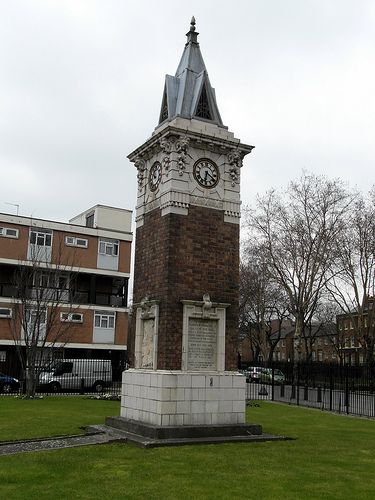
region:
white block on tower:
[157, 415, 167, 428]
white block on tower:
[173, 415, 182, 425]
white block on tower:
[163, 373, 176, 386]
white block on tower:
[178, 374, 193, 387]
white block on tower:
[191, 375, 207, 387]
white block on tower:
[207, 376, 223, 387]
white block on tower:
[220, 371, 235, 386]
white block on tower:
[234, 376, 247, 387]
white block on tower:
[166, 388, 183, 400]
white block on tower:
[193, 390, 204, 397]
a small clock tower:
[85, 13, 292, 449]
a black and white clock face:
[193, 158, 219, 189]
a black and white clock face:
[148, 159, 161, 190]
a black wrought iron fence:
[0, 358, 129, 394]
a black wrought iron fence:
[232, 365, 272, 400]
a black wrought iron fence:
[270, 365, 373, 421]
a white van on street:
[36, 358, 111, 392]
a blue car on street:
[0, 370, 19, 390]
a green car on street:
[259, 364, 284, 384]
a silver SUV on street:
[243, 366, 261, 382]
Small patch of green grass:
[284, 455, 314, 480]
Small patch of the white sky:
[84, 99, 105, 116]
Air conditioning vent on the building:
[65, 233, 89, 249]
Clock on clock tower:
[195, 159, 220, 195]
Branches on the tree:
[23, 270, 55, 302]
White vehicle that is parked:
[41, 356, 116, 393]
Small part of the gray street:
[251, 384, 259, 393]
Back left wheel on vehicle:
[95, 383, 104, 393]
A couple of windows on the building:
[310, 347, 324, 360]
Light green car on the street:
[262, 365, 286, 389]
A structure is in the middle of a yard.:
[101, 14, 270, 457]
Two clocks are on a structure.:
[125, 116, 259, 230]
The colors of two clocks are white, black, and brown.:
[145, 154, 220, 194]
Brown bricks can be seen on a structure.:
[124, 196, 246, 376]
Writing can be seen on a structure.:
[181, 303, 223, 376]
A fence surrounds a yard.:
[0, 343, 373, 427]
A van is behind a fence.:
[34, 355, 114, 396]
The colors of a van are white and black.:
[35, 355, 113, 394]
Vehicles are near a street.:
[235, 364, 287, 387]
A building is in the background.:
[0, 201, 139, 392]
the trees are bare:
[3, 242, 82, 423]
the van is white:
[38, 347, 130, 414]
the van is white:
[33, 357, 134, 390]